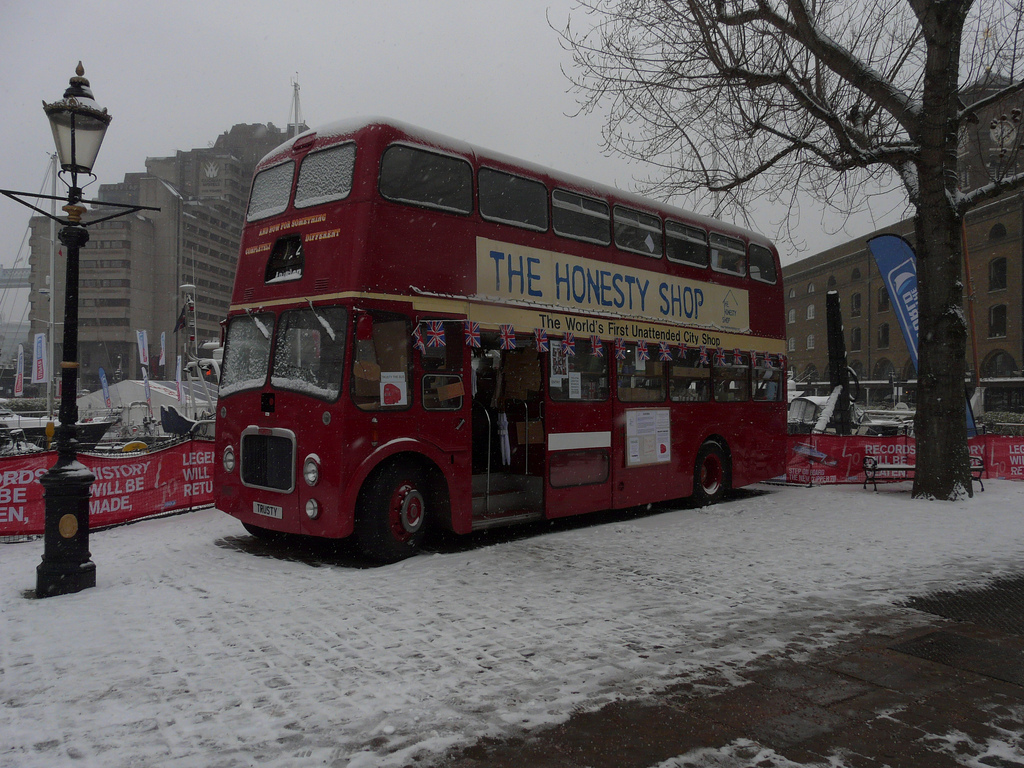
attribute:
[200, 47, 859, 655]
bus — double decker